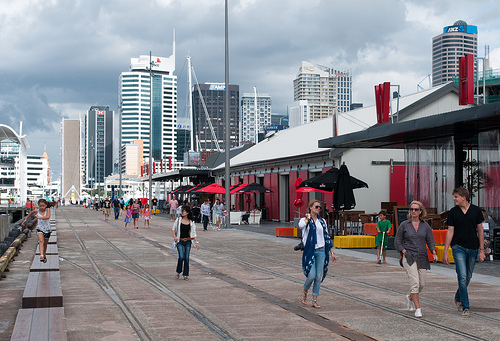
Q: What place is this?
A: It is a city.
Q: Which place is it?
A: It is a city.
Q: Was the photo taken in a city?
A: Yes, it was taken in a city.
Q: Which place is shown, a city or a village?
A: It is a city.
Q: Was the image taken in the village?
A: No, the picture was taken in the city.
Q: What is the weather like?
A: It is cloudy.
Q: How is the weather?
A: It is cloudy.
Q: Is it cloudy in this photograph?
A: Yes, it is cloudy.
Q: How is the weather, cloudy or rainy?
A: It is cloudy.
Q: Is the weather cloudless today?
A: No, it is cloudy.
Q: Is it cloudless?
A: No, it is cloudy.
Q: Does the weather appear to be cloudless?
A: No, it is cloudy.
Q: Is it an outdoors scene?
A: Yes, it is outdoors.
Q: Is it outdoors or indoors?
A: It is outdoors.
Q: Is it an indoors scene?
A: No, it is outdoors.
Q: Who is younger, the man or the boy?
A: The boy is younger than the man.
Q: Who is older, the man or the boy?
A: The man is older than the boy.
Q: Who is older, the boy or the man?
A: The man is older than the boy.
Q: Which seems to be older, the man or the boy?
A: The man is older than the boy.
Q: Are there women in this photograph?
A: Yes, there is a woman.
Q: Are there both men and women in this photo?
A: Yes, there are both a woman and a man.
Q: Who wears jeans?
A: The woman wears jeans.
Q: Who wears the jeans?
A: The woman wears jeans.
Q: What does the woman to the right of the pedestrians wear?
A: The woman wears jeans.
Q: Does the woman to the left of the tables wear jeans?
A: Yes, the woman wears jeans.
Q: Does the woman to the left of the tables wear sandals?
A: No, the woman wears jeans.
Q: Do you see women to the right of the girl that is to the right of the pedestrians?
A: Yes, there is a woman to the right of the girl.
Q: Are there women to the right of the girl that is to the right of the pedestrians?
A: Yes, there is a woman to the right of the girl.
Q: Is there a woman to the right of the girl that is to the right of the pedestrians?
A: Yes, there is a woman to the right of the girl.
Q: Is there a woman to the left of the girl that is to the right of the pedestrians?
A: No, the woman is to the right of the girl.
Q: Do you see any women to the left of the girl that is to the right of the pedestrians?
A: No, the woman is to the right of the girl.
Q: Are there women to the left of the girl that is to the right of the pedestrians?
A: No, the woman is to the right of the girl.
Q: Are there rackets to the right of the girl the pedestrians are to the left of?
A: No, there is a woman to the right of the girl.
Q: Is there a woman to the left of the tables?
A: Yes, there is a woman to the left of the tables.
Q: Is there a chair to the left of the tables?
A: No, there is a woman to the left of the tables.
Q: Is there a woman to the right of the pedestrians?
A: Yes, there is a woman to the right of the pedestrians.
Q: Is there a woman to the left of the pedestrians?
A: No, the woman is to the right of the pedestrians.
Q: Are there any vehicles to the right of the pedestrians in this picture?
A: No, there is a woman to the right of the pedestrians.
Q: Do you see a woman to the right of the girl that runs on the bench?
A: Yes, there is a woman to the right of the girl.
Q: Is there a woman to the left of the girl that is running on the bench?
A: No, the woman is to the right of the girl.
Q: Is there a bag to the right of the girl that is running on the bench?
A: No, there is a woman to the right of the girl.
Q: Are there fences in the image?
A: No, there are no fences.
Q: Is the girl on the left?
A: Yes, the girl is on the left of the image.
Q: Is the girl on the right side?
A: No, the girl is on the left of the image.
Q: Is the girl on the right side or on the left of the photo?
A: The girl is on the left of the image.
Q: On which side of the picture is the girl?
A: The girl is on the left of the image.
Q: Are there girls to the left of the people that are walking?
A: Yes, there is a girl to the left of the people.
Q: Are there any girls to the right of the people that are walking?
A: No, the girl is to the left of the people.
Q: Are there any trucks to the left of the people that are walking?
A: No, there is a girl to the left of the people.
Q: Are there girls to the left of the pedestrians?
A: Yes, there is a girl to the left of the pedestrians.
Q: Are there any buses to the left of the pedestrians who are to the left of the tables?
A: No, there is a girl to the left of the pedestrians.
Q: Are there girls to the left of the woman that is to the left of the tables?
A: Yes, there is a girl to the left of the woman.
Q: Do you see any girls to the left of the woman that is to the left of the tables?
A: Yes, there is a girl to the left of the woman.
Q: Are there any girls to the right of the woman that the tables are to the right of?
A: No, the girl is to the left of the woman.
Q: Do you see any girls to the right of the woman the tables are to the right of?
A: No, the girl is to the left of the woman.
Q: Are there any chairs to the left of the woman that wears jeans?
A: No, there is a girl to the left of the woman.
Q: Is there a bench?
A: Yes, there is a bench.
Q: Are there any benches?
A: Yes, there is a bench.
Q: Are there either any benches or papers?
A: Yes, there is a bench.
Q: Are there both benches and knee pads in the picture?
A: No, there is a bench but no knee pads.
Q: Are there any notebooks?
A: No, there are no notebooks.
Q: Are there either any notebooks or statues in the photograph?
A: No, there are no notebooks or statues.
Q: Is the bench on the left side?
A: Yes, the bench is on the left of the image.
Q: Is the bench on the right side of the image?
A: No, the bench is on the left of the image.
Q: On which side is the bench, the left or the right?
A: The bench is on the left of the image.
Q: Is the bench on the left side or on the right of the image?
A: The bench is on the left of the image.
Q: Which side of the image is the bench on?
A: The bench is on the left of the image.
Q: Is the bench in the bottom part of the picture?
A: Yes, the bench is in the bottom of the image.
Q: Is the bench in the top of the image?
A: No, the bench is in the bottom of the image.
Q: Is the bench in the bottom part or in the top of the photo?
A: The bench is in the bottom of the image.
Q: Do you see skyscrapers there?
A: Yes, there are skyscrapers.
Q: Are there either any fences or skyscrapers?
A: Yes, there are skyscrapers.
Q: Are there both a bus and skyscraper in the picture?
A: No, there are skyscrapers but no buses.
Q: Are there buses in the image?
A: No, there are no buses.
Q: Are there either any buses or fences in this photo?
A: No, there are no buses or fences.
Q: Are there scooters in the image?
A: Yes, there is a scooter.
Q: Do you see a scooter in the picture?
A: Yes, there is a scooter.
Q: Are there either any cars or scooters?
A: Yes, there is a scooter.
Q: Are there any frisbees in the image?
A: No, there are no frisbees.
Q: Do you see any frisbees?
A: No, there are no frisbees.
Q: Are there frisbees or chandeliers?
A: No, there are no frisbees or chandeliers.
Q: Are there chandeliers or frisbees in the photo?
A: No, there are no frisbees or chandeliers.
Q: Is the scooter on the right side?
A: Yes, the scooter is on the right of the image.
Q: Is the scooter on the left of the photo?
A: No, the scooter is on the right of the image.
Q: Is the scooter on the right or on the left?
A: The scooter is on the right of the image.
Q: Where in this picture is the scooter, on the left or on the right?
A: The scooter is on the right of the image.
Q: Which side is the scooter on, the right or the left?
A: The scooter is on the right of the image.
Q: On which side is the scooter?
A: The scooter is on the right of the image.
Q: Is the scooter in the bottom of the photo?
A: Yes, the scooter is in the bottom of the image.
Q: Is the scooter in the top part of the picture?
A: No, the scooter is in the bottom of the image.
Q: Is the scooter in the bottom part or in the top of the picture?
A: The scooter is in the bottom of the image.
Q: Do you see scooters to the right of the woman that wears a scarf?
A: Yes, there is a scooter to the right of the woman.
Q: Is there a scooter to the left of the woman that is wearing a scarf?
A: No, the scooter is to the right of the woman.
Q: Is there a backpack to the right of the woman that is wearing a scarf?
A: No, there is a scooter to the right of the woman.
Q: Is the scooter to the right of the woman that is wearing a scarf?
A: Yes, the scooter is to the right of the woman.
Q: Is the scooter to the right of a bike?
A: No, the scooter is to the right of the woman.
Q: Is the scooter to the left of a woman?
A: No, the scooter is to the right of a woman.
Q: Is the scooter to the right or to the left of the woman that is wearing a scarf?
A: The scooter is to the right of the woman.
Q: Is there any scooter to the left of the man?
A: Yes, there is a scooter to the left of the man.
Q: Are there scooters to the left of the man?
A: Yes, there is a scooter to the left of the man.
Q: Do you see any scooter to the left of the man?
A: Yes, there is a scooter to the left of the man.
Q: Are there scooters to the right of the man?
A: No, the scooter is to the left of the man.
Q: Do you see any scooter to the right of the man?
A: No, the scooter is to the left of the man.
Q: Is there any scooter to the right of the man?
A: No, the scooter is to the left of the man.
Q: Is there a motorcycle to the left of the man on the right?
A: No, there is a scooter to the left of the man.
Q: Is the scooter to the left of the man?
A: Yes, the scooter is to the left of the man.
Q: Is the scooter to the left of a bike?
A: No, the scooter is to the left of the man.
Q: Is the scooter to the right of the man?
A: No, the scooter is to the left of the man.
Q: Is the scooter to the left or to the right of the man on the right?
A: The scooter is to the left of the man.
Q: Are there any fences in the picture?
A: No, there are no fences.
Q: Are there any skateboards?
A: No, there are no skateboards.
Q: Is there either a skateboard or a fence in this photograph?
A: No, there are no skateboards or fences.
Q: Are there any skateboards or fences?
A: No, there are no skateboards or fences.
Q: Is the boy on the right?
A: Yes, the boy is on the right of the image.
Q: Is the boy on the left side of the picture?
A: No, the boy is on the right of the image.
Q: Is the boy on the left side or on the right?
A: The boy is on the right of the image.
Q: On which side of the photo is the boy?
A: The boy is on the right of the image.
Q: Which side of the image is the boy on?
A: The boy is on the right of the image.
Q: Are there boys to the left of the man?
A: Yes, there is a boy to the left of the man.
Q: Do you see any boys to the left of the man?
A: Yes, there is a boy to the left of the man.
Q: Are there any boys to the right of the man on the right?
A: No, the boy is to the left of the man.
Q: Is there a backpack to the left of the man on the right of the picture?
A: No, there is a boy to the left of the man.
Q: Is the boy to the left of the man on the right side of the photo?
A: Yes, the boy is to the left of the man.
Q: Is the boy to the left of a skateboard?
A: No, the boy is to the left of the man.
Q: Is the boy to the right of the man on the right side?
A: No, the boy is to the left of the man.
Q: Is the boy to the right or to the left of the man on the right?
A: The boy is to the left of the man.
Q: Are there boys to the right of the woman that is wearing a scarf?
A: Yes, there is a boy to the right of the woman.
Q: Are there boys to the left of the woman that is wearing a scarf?
A: No, the boy is to the right of the woman.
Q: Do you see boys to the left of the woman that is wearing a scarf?
A: No, the boy is to the right of the woman.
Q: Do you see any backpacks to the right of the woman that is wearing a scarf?
A: No, there is a boy to the right of the woman.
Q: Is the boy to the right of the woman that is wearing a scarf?
A: Yes, the boy is to the right of the woman.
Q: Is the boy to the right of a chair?
A: No, the boy is to the right of the woman.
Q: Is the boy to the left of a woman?
A: No, the boy is to the right of a woman.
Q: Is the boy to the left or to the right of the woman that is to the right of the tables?
A: The boy is to the right of the woman.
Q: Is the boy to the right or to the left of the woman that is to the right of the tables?
A: The boy is to the right of the woman.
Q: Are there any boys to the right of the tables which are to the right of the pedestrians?
A: Yes, there is a boy to the right of the tables.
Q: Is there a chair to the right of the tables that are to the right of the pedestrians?
A: No, there is a boy to the right of the tables.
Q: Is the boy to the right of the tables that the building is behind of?
A: Yes, the boy is to the right of the tables.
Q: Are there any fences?
A: No, there are no fences.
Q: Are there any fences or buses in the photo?
A: No, there are no fences or buses.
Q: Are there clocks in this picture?
A: No, there are no clocks.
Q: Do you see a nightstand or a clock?
A: No, there are no clocks or nightstands.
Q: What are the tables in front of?
A: The tables are in front of the building.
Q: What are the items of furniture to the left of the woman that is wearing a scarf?
A: The pieces of furniture are tables.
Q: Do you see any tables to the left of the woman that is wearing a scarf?
A: Yes, there are tables to the left of the woman.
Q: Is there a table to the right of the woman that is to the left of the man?
A: No, the tables are to the left of the woman.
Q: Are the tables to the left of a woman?
A: Yes, the tables are to the left of a woman.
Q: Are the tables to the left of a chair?
A: No, the tables are to the left of a woman.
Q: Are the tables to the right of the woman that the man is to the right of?
A: No, the tables are to the left of the woman.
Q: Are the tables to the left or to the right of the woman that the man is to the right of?
A: The tables are to the left of the woman.